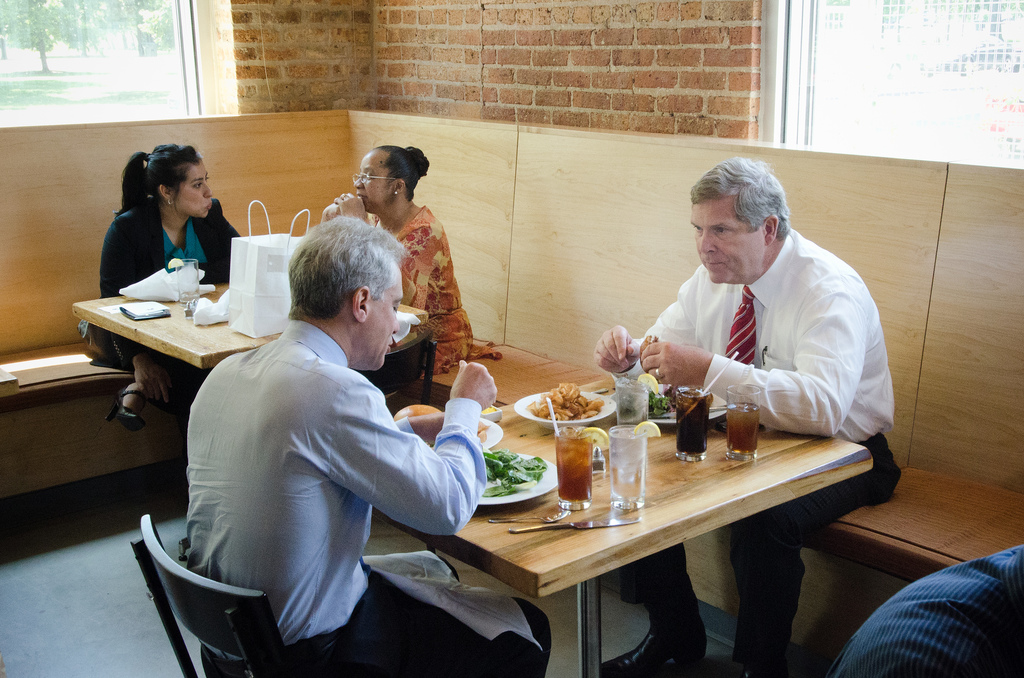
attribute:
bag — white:
[131, 178, 382, 358]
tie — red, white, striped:
[684, 301, 805, 429]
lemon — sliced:
[600, 415, 726, 448]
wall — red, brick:
[444, 16, 838, 161]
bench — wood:
[520, 102, 989, 465]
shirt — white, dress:
[682, 275, 912, 425]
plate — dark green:
[375, 448, 656, 537]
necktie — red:
[675, 299, 790, 405]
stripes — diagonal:
[727, 301, 775, 360]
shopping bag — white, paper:
[209, 210, 272, 338]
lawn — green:
[29, 76, 75, 107]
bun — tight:
[385, 145, 438, 195]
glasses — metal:
[347, 180, 393, 196]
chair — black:
[103, 539, 302, 660]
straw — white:
[675, 363, 755, 424]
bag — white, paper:
[221, 212, 284, 312]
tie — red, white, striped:
[718, 286, 764, 380]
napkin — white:
[386, 569, 505, 650]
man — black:
[649, 169, 878, 420]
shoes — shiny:
[634, 634, 723, 674]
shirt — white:
[720, 295, 928, 416]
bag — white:
[227, 198, 314, 349]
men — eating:
[172, 208, 565, 669]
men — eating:
[596, 153, 911, 668]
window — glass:
[6, 5, 232, 125]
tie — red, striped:
[718, 290, 765, 371]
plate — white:
[477, 441, 558, 516]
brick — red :
[258, 38, 306, 69]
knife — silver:
[498, 508, 619, 552]